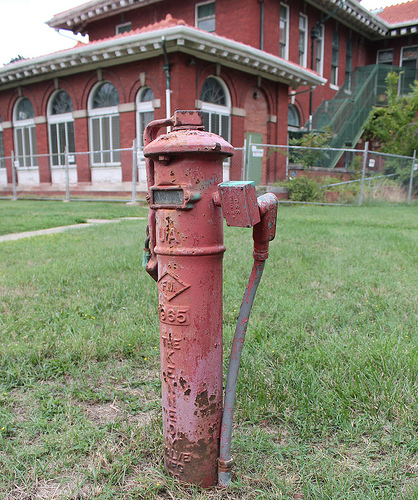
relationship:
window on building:
[8, 92, 42, 185] [4, 1, 415, 202]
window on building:
[79, 79, 120, 170] [0, 43, 298, 179]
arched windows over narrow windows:
[0, 77, 157, 122] [0, 111, 156, 186]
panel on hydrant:
[144, 177, 207, 211] [129, 87, 246, 444]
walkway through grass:
[6, 199, 114, 268] [325, 225, 363, 280]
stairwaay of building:
[289, 60, 398, 167] [28, 20, 399, 178]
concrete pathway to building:
[37, 204, 131, 241] [12, 6, 333, 212]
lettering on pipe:
[155, 306, 191, 327] [143, 71, 284, 454]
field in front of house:
[9, 192, 416, 470] [4, 0, 416, 241]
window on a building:
[136, 86, 157, 147] [4, 1, 415, 202]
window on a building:
[12, 100, 38, 169] [4, 1, 415, 202]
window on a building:
[46, 88, 74, 167] [4, 1, 415, 202]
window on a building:
[85, 79, 119, 166] [4, 1, 415, 202]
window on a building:
[198, 75, 233, 161] [4, 1, 415, 202]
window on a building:
[130, 82, 157, 149] [4, 1, 415, 202]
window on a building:
[40, 88, 85, 187] [4, 41, 369, 196]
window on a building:
[198, 75, 231, 164] [4, 45, 414, 203]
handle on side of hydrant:
[139, 116, 182, 273] [144, 109, 272, 489]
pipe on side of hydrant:
[215, 247, 272, 490] [144, 109, 272, 489]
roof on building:
[4, 13, 317, 83] [30, 23, 366, 198]